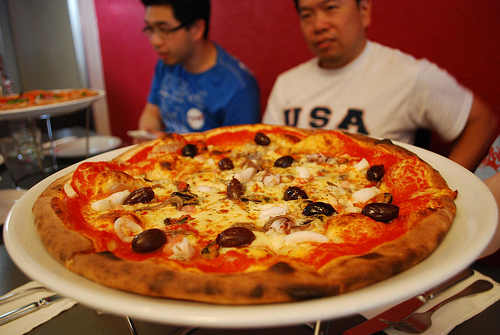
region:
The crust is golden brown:
[42, 143, 457, 296]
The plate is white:
[276, 245, 476, 323]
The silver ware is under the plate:
[341, 278, 486, 331]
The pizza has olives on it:
[101, 206, 185, 269]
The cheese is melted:
[148, 211, 310, 282]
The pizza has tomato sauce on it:
[71, 206, 167, 278]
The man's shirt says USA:
[263, 66, 410, 148]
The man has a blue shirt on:
[123, 66, 295, 173]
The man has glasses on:
[129, 12, 206, 64]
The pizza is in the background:
[1, 70, 168, 185]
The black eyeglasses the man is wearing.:
[134, 15, 186, 38]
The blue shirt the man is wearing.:
[149, 69, 256, 119]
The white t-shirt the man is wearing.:
[264, 52, 461, 142]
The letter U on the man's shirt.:
[275, 102, 305, 129]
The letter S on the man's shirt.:
[307, 101, 332, 134]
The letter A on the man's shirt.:
[339, 99, 374, 130]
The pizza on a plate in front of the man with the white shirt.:
[57, 119, 450, 306]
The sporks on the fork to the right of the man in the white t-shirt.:
[389, 305, 431, 332]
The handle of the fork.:
[418, 273, 496, 318]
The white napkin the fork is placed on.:
[367, 285, 497, 331]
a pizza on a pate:
[67, 137, 397, 312]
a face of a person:
[299, 1, 350, 51]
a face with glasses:
[137, 6, 191, 63]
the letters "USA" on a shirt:
[285, 100, 374, 129]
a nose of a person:
[308, 13, 335, 37]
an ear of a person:
[355, 6, 377, 32]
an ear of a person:
[191, 15, 211, 44]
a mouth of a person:
[312, 36, 343, 51]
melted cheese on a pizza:
[281, 232, 324, 253]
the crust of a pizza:
[291, 261, 344, 303]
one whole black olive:
[127, 227, 169, 254]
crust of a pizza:
[132, 263, 344, 304]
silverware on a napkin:
[2, 278, 64, 324]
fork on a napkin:
[377, 276, 490, 333]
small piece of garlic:
[341, 178, 393, 215]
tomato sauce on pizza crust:
[387, 178, 442, 280]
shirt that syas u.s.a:
[267, 56, 420, 139]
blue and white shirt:
[104, 60, 249, 128]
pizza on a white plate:
[7, 71, 112, 118]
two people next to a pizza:
[112, 10, 423, 278]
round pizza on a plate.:
[2, 117, 495, 317]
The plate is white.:
[4, 130, 495, 318]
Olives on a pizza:
[91, 125, 446, 262]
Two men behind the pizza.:
[99, 0, 491, 179]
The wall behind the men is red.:
[49, 5, 492, 172]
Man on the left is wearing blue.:
[111, 40, 268, 135]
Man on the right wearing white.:
[240, 30, 476, 161]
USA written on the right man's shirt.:
[264, 100, 381, 142]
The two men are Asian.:
[95, 0, 492, 180]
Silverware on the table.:
[356, 273, 494, 330]